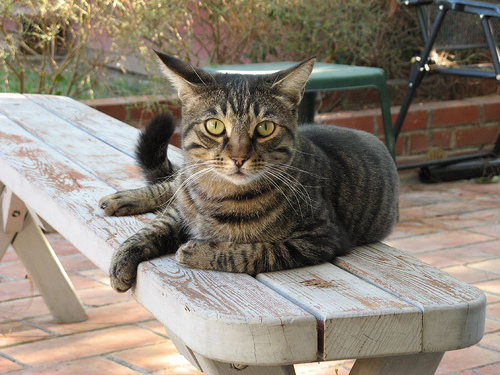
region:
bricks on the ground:
[37, 195, 487, 336]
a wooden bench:
[1, 81, 481, 366]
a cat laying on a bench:
[115, 41, 440, 342]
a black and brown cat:
[106, 54, 409, 274]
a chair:
[413, 26, 498, 139]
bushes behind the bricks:
[4, 19, 494, 70]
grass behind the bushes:
[19, 58, 104, 90]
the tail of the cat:
[131, 105, 183, 169]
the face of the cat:
[148, 49, 313, 179]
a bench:
[3, 92, 483, 362]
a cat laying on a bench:
[103, 51, 456, 349]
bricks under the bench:
[14, 310, 153, 372]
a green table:
[224, 50, 401, 138]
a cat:
[108, 48, 386, 285]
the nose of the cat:
[230, 150, 249, 165]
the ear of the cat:
[150, 46, 220, 87]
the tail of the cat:
[139, 106, 182, 183]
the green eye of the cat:
[206, 119, 226, 131]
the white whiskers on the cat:
[256, 159, 326, 214]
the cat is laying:
[95, 75, 419, 303]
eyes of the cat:
[195, 111, 285, 143]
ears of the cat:
[153, 48, 295, 100]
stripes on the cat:
[212, 194, 298, 226]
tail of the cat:
[125, 95, 166, 187]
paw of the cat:
[95, 229, 142, 298]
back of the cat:
[302, 118, 395, 150]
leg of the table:
[5, 244, 80, 334]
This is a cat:
[100, 37, 412, 305]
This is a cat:
[115, 35, 440, 348]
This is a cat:
[101, 41, 431, 299]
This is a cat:
[100, 23, 471, 371]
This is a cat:
[104, 43, 442, 308]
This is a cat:
[94, 34, 436, 321]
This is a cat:
[113, 32, 416, 317]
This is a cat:
[93, 43, 410, 320]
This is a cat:
[95, 36, 397, 313]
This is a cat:
[108, 49, 395, 344]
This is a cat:
[98, 42, 440, 309]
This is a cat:
[92, 32, 420, 318]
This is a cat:
[98, 36, 423, 333]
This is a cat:
[94, 27, 411, 333]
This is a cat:
[97, 31, 436, 335]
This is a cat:
[91, 38, 427, 327]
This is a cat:
[78, 38, 420, 321]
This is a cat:
[88, 37, 422, 313]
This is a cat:
[96, 42, 422, 322]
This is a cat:
[98, 35, 414, 301]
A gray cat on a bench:
[95, 48, 397, 293]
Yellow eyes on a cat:
[197, 117, 279, 138]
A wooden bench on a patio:
[1, 93, 485, 374]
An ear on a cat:
[270, 58, 315, 100]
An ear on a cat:
[151, 48, 206, 100]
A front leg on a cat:
[111, 210, 181, 290]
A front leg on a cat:
[177, 236, 341, 271]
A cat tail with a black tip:
[132, 111, 179, 179]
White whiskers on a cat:
[265, 160, 325, 219]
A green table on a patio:
[211, 58, 401, 155]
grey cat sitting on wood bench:
[34, 35, 426, 323]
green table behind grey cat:
[90, 46, 411, 311]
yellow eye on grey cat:
[237, 52, 317, 187]